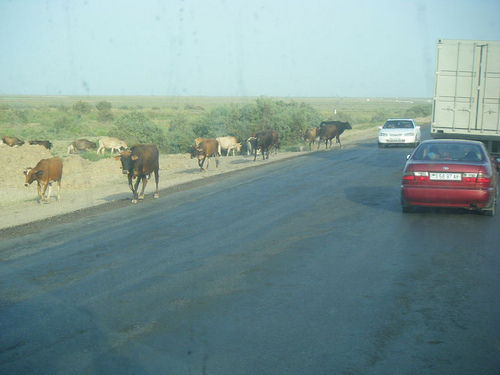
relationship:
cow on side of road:
[250, 127, 275, 156] [1, 122, 498, 374]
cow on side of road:
[319, 112, 361, 158] [1, 122, 498, 374]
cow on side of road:
[17, 147, 69, 189] [1, 122, 498, 374]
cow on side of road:
[17, 153, 69, 206] [1, 122, 498, 374]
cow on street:
[117, 142, 162, 204] [2, 119, 484, 371]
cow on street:
[17, 153, 69, 206] [2, 119, 484, 371]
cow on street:
[188, 133, 222, 172] [2, 119, 484, 371]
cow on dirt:
[17, 153, 69, 206] [0, 125, 381, 237]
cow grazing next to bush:
[95, 135, 127, 157] [105, 111, 165, 153]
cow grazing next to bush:
[95, 135, 127, 157] [155, 128, 196, 153]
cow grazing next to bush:
[95, 135, 127, 157] [166, 110, 197, 140]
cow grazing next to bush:
[95, 135, 127, 157] [184, 110, 213, 139]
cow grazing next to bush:
[95, 135, 127, 157] [226, 122, 250, 156]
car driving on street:
[364, 112, 418, 152] [2, 119, 484, 371]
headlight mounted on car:
[402, 128, 420, 138] [377, 115, 417, 144]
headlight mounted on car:
[378, 131, 388, 138] [377, 115, 417, 144]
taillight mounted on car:
[402, 169, 430, 182] [397, 138, 483, 212]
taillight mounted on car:
[458, 167, 484, 181] [397, 138, 483, 212]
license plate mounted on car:
[429, 171, 462, 181] [401, 139, 498, 213]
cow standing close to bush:
[117, 142, 159, 203] [110, 111, 157, 139]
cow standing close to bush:
[17, 153, 69, 206] [159, 130, 195, 153]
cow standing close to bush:
[95, 135, 127, 157] [187, 115, 215, 135]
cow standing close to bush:
[313, 116, 355, 152] [166, 111, 193, 134]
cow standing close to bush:
[215, 135, 241, 155] [94, 107, 113, 120]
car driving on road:
[374, 112, 424, 150] [71, 141, 481, 350]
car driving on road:
[395, 130, 498, 219] [1, 122, 498, 374]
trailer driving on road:
[428, 37, 498, 141] [1, 122, 498, 374]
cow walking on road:
[117, 142, 159, 203] [1, 122, 498, 374]